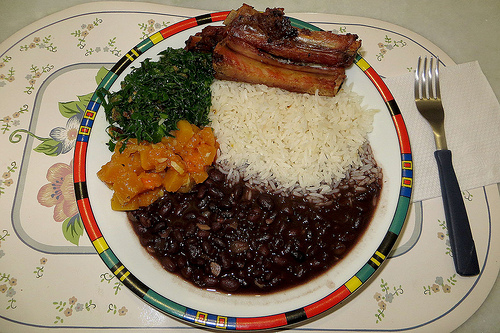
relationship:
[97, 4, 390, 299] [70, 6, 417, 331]
food on a plate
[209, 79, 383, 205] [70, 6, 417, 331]
rice on a plate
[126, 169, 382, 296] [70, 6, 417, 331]
beans on a plate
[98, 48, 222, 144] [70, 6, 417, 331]
greens on a plate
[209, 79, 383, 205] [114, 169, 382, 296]
rice and beans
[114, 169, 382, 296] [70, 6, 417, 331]
beans on a plate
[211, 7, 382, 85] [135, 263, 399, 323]
ribs on a plate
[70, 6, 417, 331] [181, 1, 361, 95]
plate of food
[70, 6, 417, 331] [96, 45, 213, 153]
plate of food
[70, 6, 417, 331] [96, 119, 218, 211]
plate of food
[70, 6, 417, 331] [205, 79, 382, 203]
plate of food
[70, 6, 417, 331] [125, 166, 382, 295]
plate of food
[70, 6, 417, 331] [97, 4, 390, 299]
plate of food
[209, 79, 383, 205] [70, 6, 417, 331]
rice on plate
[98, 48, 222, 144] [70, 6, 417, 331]
greens on plate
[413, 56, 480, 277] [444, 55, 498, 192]
fork laying on napkin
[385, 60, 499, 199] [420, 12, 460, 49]
napkin on top of table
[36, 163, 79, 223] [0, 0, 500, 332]
flower printed on food tray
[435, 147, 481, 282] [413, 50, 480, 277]
handle connected to fork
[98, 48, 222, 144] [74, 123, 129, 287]
greens on top of plate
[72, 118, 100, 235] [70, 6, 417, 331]
edge around plate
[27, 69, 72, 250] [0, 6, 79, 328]
design on top of place mat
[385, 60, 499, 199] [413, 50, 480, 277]
napkin underneath fork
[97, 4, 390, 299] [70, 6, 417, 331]
food on top of plate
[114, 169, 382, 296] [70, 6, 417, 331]
beans on top of plate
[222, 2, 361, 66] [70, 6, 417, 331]
fried meat on top of plate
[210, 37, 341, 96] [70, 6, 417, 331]
meat on top of plate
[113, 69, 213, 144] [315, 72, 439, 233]
greens on top of plate